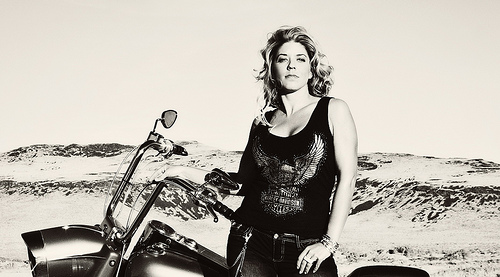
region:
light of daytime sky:
[4, 4, 495, 145]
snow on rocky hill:
[0, 142, 495, 220]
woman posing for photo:
[215, 27, 362, 275]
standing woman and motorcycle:
[26, 24, 357, 272]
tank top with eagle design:
[243, 97, 340, 237]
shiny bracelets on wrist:
[296, 233, 338, 272]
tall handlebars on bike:
[103, 144, 238, 239]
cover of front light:
[21, 222, 117, 275]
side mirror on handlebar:
[153, 108, 178, 138]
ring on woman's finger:
[294, 249, 319, 272]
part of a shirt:
[267, 161, 280, 199]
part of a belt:
[263, 223, 280, 251]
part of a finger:
[313, 233, 326, 269]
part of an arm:
[338, 192, 350, 212]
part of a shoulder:
[337, 105, 352, 112]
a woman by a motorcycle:
[23, 15, 431, 274]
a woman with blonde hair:
[230, 15, 360, 275]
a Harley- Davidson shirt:
[247, 104, 337, 241]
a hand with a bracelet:
[291, 232, 348, 274]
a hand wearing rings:
[294, 225, 333, 275]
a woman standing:
[22, 22, 397, 274]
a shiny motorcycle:
[19, 107, 437, 275]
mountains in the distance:
[368, 150, 499, 236]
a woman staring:
[227, 25, 360, 272]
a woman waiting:
[227, 22, 359, 272]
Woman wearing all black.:
[227, 25, 357, 275]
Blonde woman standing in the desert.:
[227, 26, 357, 275]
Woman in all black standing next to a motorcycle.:
[228, 27, 358, 275]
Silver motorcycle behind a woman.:
[20, 108, 430, 274]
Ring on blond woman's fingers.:
[303, 256, 311, 262]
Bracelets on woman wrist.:
[321, 234, 339, 252]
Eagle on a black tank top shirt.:
[250, 135, 325, 214]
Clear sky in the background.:
[0, 0, 499, 140]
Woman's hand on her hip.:
[296, 242, 331, 274]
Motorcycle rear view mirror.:
[161, 108, 176, 126]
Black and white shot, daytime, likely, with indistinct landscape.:
[2, 5, 499, 271]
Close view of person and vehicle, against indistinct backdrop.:
[3, 2, 498, 274]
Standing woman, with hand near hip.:
[232, 28, 336, 273]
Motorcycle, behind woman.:
[10, 111, 214, 271]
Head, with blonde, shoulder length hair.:
[261, 12, 338, 101]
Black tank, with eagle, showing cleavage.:
[249, 101, 338, 245]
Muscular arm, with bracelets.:
[323, 97, 339, 257]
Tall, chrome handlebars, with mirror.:
[105, 111, 218, 253]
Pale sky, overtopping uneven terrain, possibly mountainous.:
[10, 24, 89, 211]